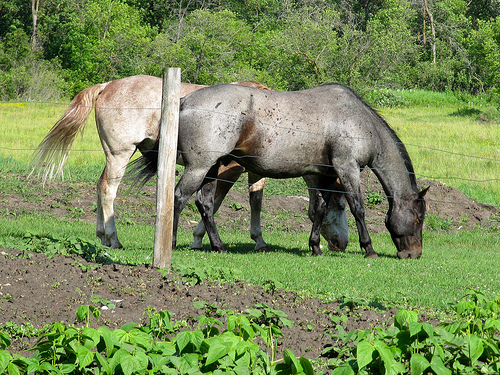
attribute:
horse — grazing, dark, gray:
[126, 82, 428, 259]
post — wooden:
[151, 67, 181, 267]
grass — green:
[2, 89, 498, 316]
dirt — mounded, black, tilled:
[271, 167, 495, 231]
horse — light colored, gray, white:
[28, 74, 349, 250]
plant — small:
[184, 266, 206, 287]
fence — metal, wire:
[0, 67, 499, 271]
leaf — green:
[103, 51, 107, 53]